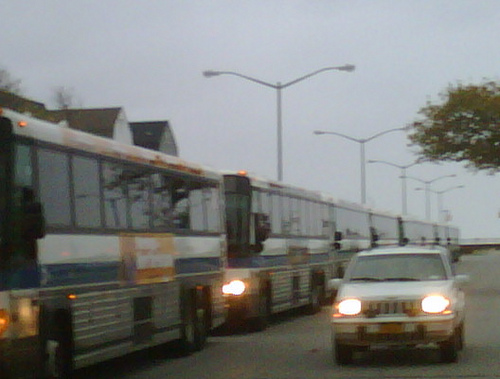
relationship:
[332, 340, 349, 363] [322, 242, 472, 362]
wheel of a car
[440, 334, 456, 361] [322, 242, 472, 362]
wheel of a car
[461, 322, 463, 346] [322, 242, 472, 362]
wheel of a car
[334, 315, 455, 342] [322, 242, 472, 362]
bumper of a car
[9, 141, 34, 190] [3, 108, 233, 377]
window on bus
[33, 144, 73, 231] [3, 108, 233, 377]
window on bus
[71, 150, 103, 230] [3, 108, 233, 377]
window on bus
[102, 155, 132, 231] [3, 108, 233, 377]
window on bus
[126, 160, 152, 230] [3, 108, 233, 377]
window on bus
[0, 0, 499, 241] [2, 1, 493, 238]
clouds in sky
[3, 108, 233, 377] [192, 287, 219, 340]
bus has wheel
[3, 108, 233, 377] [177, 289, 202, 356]
bus has wheel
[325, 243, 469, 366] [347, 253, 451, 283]
car has windshield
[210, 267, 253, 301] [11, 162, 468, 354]
headlight on bus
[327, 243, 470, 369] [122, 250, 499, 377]
car on road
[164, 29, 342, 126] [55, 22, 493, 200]
clouds in sky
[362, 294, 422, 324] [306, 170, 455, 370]
grill of a car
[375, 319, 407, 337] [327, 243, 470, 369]
license plate of a car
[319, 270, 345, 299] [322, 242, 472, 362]
mirror of a car